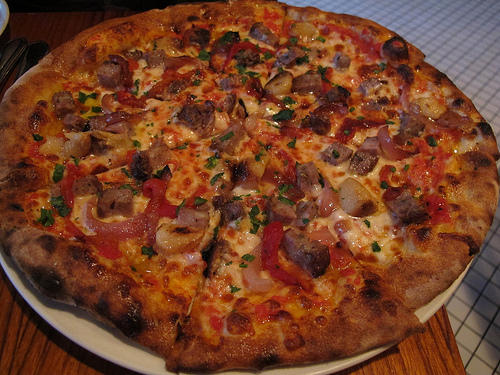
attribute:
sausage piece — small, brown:
[96, 187, 131, 218]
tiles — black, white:
[296, 1, 498, 363]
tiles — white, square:
[464, 310, 490, 335]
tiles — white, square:
[471, 63, 490, 91]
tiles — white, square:
[407, 8, 446, 33]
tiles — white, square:
[477, 4, 497, 33]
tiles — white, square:
[484, 268, 496, 296]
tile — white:
[286, 0, 495, 112]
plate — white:
[0, 258, 475, 373]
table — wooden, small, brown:
[4, 6, 468, 373]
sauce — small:
[255, 218, 319, 296]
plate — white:
[2, 56, 482, 374]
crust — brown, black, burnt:
[166, 304, 477, 366]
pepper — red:
[257, 218, 317, 293]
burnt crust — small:
[253, 350, 282, 371]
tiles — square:
[448, 313, 498, 344]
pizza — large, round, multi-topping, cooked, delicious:
[0, 2, 498, 372]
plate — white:
[407, 256, 476, 323]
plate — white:
[2, 245, 412, 373]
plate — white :
[21, 31, 481, 367]